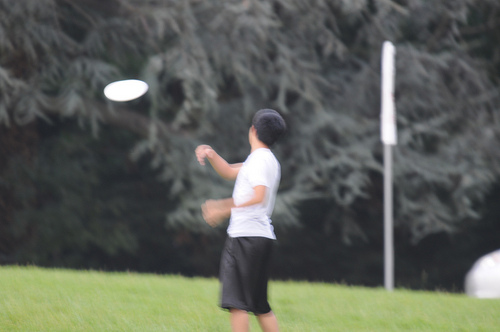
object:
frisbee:
[102, 79, 149, 102]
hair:
[252, 109, 287, 146]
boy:
[193, 107, 286, 332]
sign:
[380, 32, 396, 145]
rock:
[463, 249, 498, 299]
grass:
[0, 262, 500, 332]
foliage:
[0, 0, 500, 297]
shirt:
[226, 148, 281, 241]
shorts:
[220, 235, 278, 314]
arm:
[216, 185, 269, 215]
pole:
[379, 40, 397, 289]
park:
[2, 2, 500, 332]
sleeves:
[249, 151, 278, 189]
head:
[248, 108, 287, 149]